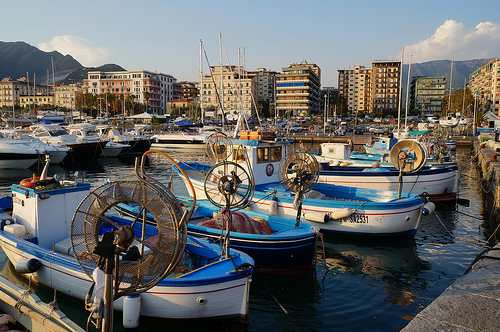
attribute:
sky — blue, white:
[3, 3, 498, 82]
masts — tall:
[0, 27, 499, 156]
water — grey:
[344, 257, 406, 311]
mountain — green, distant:
[0, 39, 128, 79]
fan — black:
[60, 180, 198, 292]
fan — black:
[195, 159, 265, 229]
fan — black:
[374, 129, 445, 187]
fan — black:
[272, 145, 344, 200]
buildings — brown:
[3, 55, 495, 140]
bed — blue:
[119, 193, 319, 240]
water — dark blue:
[0, 140, 486, 329]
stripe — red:
[184, 180, 425, 219]